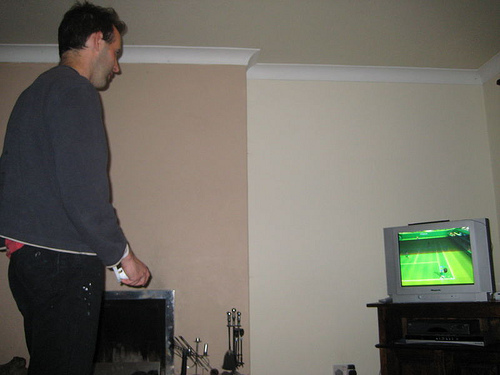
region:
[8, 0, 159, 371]
this is a person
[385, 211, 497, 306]
this is a tv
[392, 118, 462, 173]
the wall is cream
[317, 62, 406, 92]
white paint on wall border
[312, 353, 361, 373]
electrical socket on wall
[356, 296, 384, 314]
jutting edge of brown table top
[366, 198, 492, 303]
tv on top of table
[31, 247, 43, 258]
small black button on back of pants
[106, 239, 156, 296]
white remote in man's hand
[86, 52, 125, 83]
man's shaved face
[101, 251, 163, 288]
man holding a Wii controller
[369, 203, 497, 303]
TV on the stand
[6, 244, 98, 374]
man wearing black pants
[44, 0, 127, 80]
man with black hair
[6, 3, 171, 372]
Man standing in front of the TV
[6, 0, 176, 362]
Man playing a video game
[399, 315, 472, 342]
cable box in the shelf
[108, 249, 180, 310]
man holding a game controller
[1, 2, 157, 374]
this is a person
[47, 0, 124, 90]
this is a person's head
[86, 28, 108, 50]
this is a person's ear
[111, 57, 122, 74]
this is a person's nose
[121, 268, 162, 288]
this is a person's fingers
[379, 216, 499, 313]
this is a television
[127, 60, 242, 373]
this is a wall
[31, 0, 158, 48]
man has brown hair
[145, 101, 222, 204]
tan wall behind man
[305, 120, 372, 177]
white wall near tv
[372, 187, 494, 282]
grey frame on tv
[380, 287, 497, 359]
tv on brown desk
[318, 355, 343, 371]
white outlet near tv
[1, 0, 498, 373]
ceiling and wall of room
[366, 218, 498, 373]
television on top of stand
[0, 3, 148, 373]
side of standing brunette male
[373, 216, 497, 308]
An outdated TV set.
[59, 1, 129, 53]
Dark human hair.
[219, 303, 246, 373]
A set of fireplace pokers.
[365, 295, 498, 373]
A small wooden entertainment center.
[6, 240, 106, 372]
A black pair of pants.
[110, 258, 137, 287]
A white gaming controller.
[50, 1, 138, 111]
the head of a man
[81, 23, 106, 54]
the hear of a man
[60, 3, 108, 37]
the hair of a man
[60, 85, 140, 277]
the arm of a man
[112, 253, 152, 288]
the hand of a man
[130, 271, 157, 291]
the fingers of a man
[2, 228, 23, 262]
the undershirt of a man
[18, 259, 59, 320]
the pockets of a man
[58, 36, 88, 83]
the neck of a man